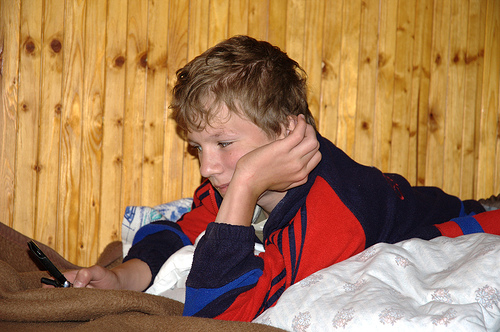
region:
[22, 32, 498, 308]
the boy is holding a cell phone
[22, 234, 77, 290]
The phone is black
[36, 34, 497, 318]
The boy is lying down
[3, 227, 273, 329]
The blanket is brown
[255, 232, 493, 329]
The blanket is white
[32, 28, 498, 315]
Boy is wearing a blue and red sweater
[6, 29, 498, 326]
The boy is on top of the blankets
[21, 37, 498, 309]
The boy is looking at the cell phone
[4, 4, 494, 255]
Brown panels on the wall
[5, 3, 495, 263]
The wall is wood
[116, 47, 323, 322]
a boy propping up his head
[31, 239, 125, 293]
a cellphone in the boy's right hand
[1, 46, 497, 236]
a wooden wall next to the boy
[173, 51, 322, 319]
propping up head with his left hand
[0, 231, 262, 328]
the blanket is brown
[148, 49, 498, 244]
a boy laying on his stomach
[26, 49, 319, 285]
a boy looking toward a phone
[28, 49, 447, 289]
a black phone in the boy's hand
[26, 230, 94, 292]
a black flip phone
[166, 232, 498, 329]
a boy laying on a pillow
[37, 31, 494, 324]
boy looking at cell phone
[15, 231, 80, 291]
cell phone is black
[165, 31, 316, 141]
boy has blonde hair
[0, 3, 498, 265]
wood panels in background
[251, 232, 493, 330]
white patterned pillow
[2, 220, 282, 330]
dark brown blanket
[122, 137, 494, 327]
boy wearing blue and red sweater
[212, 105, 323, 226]
boy's right hand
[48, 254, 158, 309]
boy's left hand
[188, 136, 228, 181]
boy has nose on face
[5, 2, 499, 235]
The wall is brown.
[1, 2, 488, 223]
The wall is wood paneling.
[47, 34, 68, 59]
A brown knot in the wood.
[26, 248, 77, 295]
The phone is black.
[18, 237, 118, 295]
He is holding the phone.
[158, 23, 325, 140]
His hair is brown.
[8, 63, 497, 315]
The boy is young.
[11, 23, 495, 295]
The boy is laying down.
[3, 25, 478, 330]
He is playing on his phone.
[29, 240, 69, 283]
The cell phone is black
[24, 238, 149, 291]
A cell phone in the right hand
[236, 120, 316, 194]
The left hand of the boy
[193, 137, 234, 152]
The eyes of the boy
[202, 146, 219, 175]
The nose of the boy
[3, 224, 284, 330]
A brown sheet below the cell phone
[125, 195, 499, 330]
A pillow beneath the boy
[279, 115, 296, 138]
The left ear of the boy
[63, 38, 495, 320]
A boy lying on a bed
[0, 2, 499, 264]
The wall behind the boy